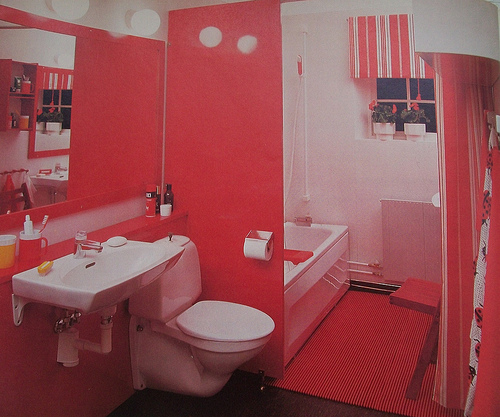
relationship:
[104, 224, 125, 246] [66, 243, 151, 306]
soap on basin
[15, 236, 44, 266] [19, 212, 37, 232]
cup has tube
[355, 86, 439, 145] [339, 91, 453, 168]
plant in window sill